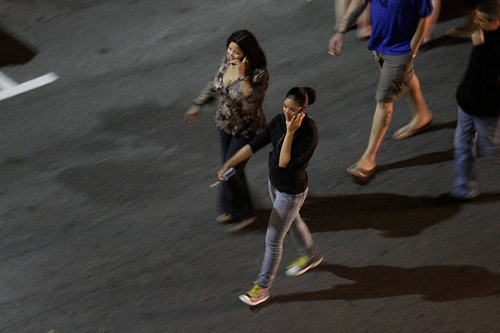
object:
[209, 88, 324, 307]
women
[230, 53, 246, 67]
phone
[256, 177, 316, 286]
jeans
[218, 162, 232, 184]
hand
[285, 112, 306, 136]
hand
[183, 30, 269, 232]
woman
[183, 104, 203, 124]
hand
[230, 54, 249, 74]
hand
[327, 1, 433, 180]
man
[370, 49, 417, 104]
shorts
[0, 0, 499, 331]
road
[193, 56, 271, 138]
blouse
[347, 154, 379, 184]
sandals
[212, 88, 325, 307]
people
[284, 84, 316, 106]
hair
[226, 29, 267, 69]
hair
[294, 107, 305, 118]
phone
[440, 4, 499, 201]
man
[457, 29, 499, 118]
shirt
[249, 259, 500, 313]
shadows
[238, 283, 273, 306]
shoes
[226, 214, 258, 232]
shoes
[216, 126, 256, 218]
pants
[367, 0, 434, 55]
shirt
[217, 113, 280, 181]
arm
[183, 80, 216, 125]
arm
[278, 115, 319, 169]
arm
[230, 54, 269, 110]
arm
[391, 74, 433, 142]
leg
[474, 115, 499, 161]
leg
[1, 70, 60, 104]
line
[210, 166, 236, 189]
purse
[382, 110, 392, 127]
tattoo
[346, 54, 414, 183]
leg